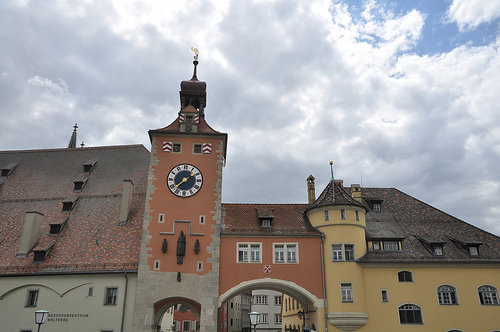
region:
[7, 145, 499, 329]
this is a house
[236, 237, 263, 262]
this is a window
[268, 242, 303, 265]
this is a window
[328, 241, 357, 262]
this is a window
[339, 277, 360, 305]
this is a window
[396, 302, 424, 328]
this is a window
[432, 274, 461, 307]
this is a window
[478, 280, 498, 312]
this is a window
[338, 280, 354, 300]
this is a window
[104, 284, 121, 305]
this is a window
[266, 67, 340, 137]
this is a cloud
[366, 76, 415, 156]
this is a cloud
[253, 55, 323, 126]
this is a cloud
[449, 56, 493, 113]
this is a cloud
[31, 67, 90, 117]
this is a cloud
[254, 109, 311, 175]
this is a cloud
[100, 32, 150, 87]
this is a cloud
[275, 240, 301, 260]
this is a window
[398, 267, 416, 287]
this is a window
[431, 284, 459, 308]
this is a window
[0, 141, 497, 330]
this is a house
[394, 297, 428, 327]
this is a window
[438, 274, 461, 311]
this is a window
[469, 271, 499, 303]
this is a window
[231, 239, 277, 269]
this is a window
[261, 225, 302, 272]
this is a window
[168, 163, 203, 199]
this is a clock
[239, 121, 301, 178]
this is a cloud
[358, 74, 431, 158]
this is a cloud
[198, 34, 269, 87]
this is a cloud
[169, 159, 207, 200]
A clock in the photo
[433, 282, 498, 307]
Windows in the photo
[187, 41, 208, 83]
A flag on top of the house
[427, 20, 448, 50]
Clear skies in the photo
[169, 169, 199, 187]
Arms of a clock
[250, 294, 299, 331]
Entrance to the building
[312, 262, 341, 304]
A pipe on the house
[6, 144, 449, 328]
this is a house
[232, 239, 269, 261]
this is a window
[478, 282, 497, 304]
this is a window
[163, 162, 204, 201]
this is a clock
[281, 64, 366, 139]
this is a cloud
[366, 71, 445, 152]
this is a cloud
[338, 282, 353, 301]
A window on a building.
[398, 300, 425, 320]
A window on a building.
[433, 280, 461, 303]
A window on a building.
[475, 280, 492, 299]
A window on a building.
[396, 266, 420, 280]
A window on a building.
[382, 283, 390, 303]
A window on a building.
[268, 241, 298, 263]
A window on a building.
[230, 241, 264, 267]
A window on a building.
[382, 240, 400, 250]
A window on a building.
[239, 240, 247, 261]
building has a window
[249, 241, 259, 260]
building has a window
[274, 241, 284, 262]
building has a window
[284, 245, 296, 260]
building has a window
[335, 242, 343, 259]
building has a window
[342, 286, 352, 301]
building has a window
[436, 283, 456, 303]
building has a window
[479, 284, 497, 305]
building has a window